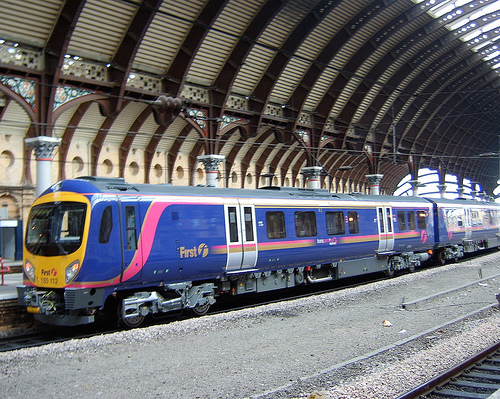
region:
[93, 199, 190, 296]
stripe on the train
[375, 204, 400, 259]
door on the train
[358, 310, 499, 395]
gravel on the tracks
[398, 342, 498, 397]
rail of the track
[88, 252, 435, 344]
wheels on the train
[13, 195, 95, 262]
front window of the train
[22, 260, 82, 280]
lights on the train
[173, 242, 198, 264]
words on the train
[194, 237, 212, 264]
logo on the train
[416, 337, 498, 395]
tracks for the train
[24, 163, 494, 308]
train on the track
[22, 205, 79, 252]
window on the train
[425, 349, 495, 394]
track train is not on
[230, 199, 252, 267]
doors on the train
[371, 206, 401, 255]
doors on the train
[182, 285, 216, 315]
wheels on the train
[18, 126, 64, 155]
decoration on top of column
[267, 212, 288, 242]
window on the train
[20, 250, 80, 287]
lights on the front car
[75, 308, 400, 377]
pavement between the track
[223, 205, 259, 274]
a silver metal train door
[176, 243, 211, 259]
a logo on the side of a train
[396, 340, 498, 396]
the corner of a railroad track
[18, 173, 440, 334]
a long blue train car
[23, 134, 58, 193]
a white decorative collumn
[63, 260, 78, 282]
headlights on the front of a train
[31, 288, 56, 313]
a metal winch on the front of a train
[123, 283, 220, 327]
metal wheels of a train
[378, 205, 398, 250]
silver metal double doors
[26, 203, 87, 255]
front windshield of a train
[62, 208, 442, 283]
pink stripe on train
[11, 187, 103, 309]
yellow face on train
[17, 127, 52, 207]
grey pillars behind train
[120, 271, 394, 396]
grey path beside train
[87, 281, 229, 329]
black wheels on train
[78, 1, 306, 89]
ceiling is light brown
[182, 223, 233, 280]
yellow logo on train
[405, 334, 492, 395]
dark brown train track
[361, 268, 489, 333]
grey pipe on ground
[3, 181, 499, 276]
A train on tracks.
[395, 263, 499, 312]
Bar in the meridian.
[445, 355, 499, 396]
The tracks are brown and grey.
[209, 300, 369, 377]
Gravel in the meridian.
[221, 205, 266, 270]
The doors are white.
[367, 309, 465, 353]
Trash in the meridian.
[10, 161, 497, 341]
train stopped on tracks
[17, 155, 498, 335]
train on tracks is blue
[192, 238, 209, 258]
logo on side of train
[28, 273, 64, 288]
number on front of train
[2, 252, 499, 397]
gravel between train tracks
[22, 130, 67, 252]
white column by front of train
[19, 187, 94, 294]
front of train is yellow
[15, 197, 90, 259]
large windshield on front of train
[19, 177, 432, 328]
a blue train engine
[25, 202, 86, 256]
a train front windshield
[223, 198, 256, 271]
train double passenger doors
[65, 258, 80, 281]
a train front headlight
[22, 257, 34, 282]
a train front headlight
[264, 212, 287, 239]
a train passenger window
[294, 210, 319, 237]
a train passenger window